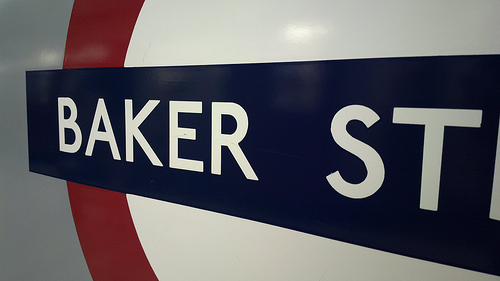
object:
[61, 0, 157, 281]
circle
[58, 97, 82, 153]
letter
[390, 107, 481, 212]
letter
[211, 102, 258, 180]
letter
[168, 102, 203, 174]
letter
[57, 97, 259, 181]
baker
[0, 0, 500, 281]
white background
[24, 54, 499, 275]
blue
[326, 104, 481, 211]
st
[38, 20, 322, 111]
glare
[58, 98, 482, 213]
background